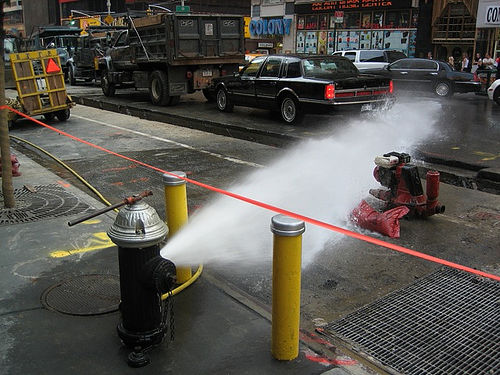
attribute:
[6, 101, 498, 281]
tape — red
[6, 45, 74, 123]
trailer — parked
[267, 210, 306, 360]
pole — yellow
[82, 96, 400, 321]
lane — closed, left lane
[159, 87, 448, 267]
water — spraying out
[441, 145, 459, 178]
ground — grey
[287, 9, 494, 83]
store — on the right side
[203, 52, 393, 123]
car — black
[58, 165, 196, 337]
hydrant — black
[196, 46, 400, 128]
car — black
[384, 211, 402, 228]
ground — silver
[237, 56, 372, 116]
car — black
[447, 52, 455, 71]
person — walking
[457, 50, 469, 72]
person — walking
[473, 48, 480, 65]
person — walking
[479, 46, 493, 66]
person — walking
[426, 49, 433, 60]
person — walking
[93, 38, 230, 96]
dump truck — large, dark, colored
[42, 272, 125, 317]
black manhole — black , a cover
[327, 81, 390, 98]
light — green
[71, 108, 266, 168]
lane marking — white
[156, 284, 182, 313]
chain — metal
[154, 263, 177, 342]
chains — black 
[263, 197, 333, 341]
sign — orange, triangular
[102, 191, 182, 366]
hydrant — fire hydrant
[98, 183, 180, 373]
fire hydrant — black , opened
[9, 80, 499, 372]
street — busy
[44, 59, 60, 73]
warning sign — orange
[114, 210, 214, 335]
hydrant — black, silver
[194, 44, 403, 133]
car — black , stopped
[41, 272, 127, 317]
manhole — round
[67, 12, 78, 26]
light — stop light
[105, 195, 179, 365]
fire hydrant — black , silver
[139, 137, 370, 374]
post — yellow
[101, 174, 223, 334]
hydrant — fire hydrant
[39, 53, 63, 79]
caution sign — orange, triangle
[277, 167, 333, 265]
water — spraying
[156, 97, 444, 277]
water — gushing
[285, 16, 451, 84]
window — covered up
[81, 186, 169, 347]
fire hydrant — black 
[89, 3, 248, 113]
dump truck — dirty